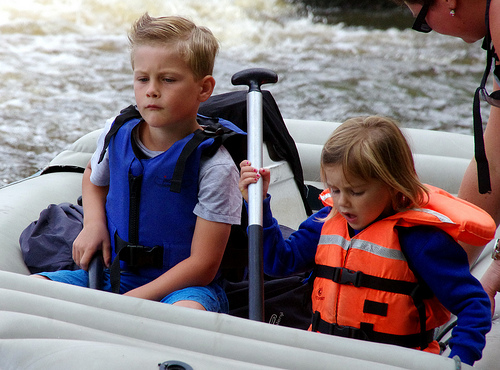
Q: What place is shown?
A: It is a river.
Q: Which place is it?
A: It is a river.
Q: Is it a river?
A: Yes, it is a river.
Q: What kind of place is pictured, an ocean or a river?
A: It is a river.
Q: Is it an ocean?
A: No, it is a river.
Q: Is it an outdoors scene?
A: Yes, it is outdoors.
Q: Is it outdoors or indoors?
A: It is outdoors.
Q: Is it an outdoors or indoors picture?
A: It is outdoors.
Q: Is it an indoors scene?
A: No, it is outdoors.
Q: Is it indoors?
A: No, it is outdoors.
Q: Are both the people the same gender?
A: No, they are both male and female.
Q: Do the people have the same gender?
A: No, they are both male and female.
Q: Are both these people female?
A: No, they are both male and female.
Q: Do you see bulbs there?
A: No, there are no bulbs.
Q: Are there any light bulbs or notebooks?
A: No, there are no light bulbs or notebooks.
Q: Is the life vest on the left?
A: No, the life vest is on the right of the image.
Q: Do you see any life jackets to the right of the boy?
A: Yes, there is a life jacket to the right of the boy.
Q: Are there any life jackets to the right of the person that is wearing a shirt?
A: Yes, there is a life jacket to the right of the boy.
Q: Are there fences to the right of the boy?
A: No, there is a life jacket to the right of the boy.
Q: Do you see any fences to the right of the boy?
A: No, there is a life jacket to the right of the boy.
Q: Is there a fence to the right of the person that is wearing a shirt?
A: No, there is a life jacket to the right of the boy.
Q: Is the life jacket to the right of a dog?
A: No, the life jacket is to the right of the boy.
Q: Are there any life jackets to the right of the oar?
A: Yes, there is a life jacket to the right of the oar.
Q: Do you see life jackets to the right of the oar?
A: Yes, there is a life jacket to the right of the oar.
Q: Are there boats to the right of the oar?
A: No, there is a life jacket to the right of the oar.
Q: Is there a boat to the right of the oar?
A: No, there is a life jacket to the right of the oar.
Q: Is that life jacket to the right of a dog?
A: No, the life jacket is to the right of the oar.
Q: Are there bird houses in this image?
A: No, there are no bird houses.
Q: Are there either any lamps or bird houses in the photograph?
A: No, there are no bird houses or lamps.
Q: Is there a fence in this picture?
A: No, there are no fences.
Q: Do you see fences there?
A: No, there are no fences.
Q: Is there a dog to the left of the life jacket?
A: No, there is a boy to the left of the life jacket.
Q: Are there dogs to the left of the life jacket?
A: No, there is a boy to the left of the life jacket.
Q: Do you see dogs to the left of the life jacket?
A: No, there is a boy to the left of the life jacket.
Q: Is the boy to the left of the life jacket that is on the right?
A: Yes, the boy is to the left of the life jacket.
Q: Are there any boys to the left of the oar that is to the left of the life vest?
A: Yes, there is a boy to the left of the oar.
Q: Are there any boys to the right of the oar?
A: No, the boy is to the left of the oar.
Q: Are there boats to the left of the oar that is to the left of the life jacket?
A: No, there is a boy to the left of the paddle.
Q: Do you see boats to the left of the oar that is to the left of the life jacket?
A: No, there is a boy to the left of the paddle.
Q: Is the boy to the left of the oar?
A: Yes, the boy is to the left of the oar.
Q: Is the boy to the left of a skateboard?
A: No, the boy is to the left of the oar.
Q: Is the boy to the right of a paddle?
A: No, the boy is to the left of a paddle.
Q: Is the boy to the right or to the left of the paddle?
A: The boy is to the left of the paddle.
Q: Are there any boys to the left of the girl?
A: Yes, there is a boy to the left of the girl.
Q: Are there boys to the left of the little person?
A: Yes, there is a boy to the left of the girl.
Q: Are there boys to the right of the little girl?
A: No, the boy is to the left of the girl.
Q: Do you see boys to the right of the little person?
A: No, the boy is to the left of the girl.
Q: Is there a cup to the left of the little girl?
A: No, there is a boy to the left of the girl.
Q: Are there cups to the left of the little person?
A: No, there is a boy to the left of the girl.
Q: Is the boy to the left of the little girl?
A: Yes, the boy is to the left of the girl.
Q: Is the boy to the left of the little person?
A: Yes, the boy is to the left of the girl.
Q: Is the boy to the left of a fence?
A: No, the boy is to the left of the girl.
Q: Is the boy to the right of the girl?
A: No, the boy is to the left of the girl.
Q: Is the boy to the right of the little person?
A: No, the boy is to the left of the girl.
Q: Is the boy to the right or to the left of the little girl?
A: The boy is to the left of the girl.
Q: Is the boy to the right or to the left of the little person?
A: The boy is to the left of the girl.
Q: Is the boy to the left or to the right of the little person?
A: The boy is to the left of the girl.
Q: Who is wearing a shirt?
A: The boy is wearing a shirt.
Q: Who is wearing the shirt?
A: The boy is wearing a shirt.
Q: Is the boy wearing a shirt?
A: Yes, the boy is wearing a shirt.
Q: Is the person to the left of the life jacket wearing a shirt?
A: Yes, the boy is wearing a shirt.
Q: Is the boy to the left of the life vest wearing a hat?
A: No, the boy is wearing a shirt.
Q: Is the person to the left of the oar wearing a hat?
A: No, the boy is wearing a shirt.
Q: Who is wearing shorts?
A: The boy is wearing shorts.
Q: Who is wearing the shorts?
A: The boy is wearing shorts.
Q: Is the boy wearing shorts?
A: Yes, the boy is wearing shorts.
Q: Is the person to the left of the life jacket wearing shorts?
A: Yes, the boy is wearing shorts.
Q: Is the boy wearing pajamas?
A: No, the boy is wearing shorts.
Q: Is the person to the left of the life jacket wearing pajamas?
A: No, the boy is wearing shorts.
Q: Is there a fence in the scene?
A: No, there are no fences.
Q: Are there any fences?
A: No, there are no fences.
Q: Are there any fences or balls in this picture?
A: No, there are no fences or balls.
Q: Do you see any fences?
A: No, there are no fences.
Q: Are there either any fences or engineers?
A: No, there are no fences or engineers.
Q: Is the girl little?
A: Yes, the girl is little.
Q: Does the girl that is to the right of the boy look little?
A: Yes, the girl is little.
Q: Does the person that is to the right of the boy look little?
A: Yes, the girl is little.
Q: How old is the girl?
A: The girl is little.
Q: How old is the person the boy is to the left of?
A: The girl is little.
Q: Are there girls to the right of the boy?
A: Yes, there is a girl to the right of the boy.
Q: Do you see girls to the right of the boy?
A: Yes, there is a girl to the right of the boy.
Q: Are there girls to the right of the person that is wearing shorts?
A: Yes, there is a girl to the right of the boy.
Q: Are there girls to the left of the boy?
A: No, the girl is to the right of the boy.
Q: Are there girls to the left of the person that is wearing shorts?
A: No, the girl is to the right of the boy.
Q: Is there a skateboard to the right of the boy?
A: No, there is a girl to the right of the boy.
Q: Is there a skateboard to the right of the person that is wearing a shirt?
A: No, there is a girl to the right of the boy.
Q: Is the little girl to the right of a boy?
A: Yes, the girl is to the right of a boy.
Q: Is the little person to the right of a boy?
A: Yes, the girl is to the right of a boy.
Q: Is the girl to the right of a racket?
A: No, the girl is to the right of a boy.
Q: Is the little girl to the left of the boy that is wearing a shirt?
A: No, the girl is to the right of the boy.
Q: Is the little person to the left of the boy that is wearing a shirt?
A: No, the girl is to the right of the boy.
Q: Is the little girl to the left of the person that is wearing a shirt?
A: No, the girl is to the right of the boy.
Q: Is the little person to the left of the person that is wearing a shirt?
A: No, the girl is to the right of the boy.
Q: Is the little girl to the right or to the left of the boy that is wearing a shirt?
A: The girl is to the right of the boy.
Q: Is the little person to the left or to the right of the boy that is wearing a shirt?
A: The girl is to the right of the boy.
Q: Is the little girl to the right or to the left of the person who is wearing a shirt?
A: The girl is to the right of the boy.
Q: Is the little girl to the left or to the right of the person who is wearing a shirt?
A: The girl is to the right of the boy.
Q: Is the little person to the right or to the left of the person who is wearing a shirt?
A: The girl is to the right of the boy.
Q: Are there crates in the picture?
A: No, there are no crates.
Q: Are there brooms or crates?
A: No, there are no crates or brooms.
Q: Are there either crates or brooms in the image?
A: No, there are no crates or brooms.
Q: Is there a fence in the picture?
A: No, there are no fences.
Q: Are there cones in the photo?
A: No, there are no cones.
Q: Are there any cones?
A: No, there are no cones.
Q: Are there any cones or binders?
A: No, there are no cones or binders.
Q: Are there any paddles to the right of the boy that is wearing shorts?
A: Yes, there is a paddle to the right of the boy.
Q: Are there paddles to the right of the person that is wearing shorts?
A: Yes, there is a paddle to the right of the boy.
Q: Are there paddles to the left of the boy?
A: No, the paddle is to the right of the boy.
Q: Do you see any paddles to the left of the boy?
A: No, the paddle is to the right of the boy.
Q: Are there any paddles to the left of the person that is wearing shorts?
A: No, the paddle is to the right of the boy.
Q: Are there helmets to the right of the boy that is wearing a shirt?
A: No, there is a paddle to the right of the boy.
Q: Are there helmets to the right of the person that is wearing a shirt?
A: No, there is a paddle to the right of the boy.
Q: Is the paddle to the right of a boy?
A: Yes, the paddle is to the right of a boy.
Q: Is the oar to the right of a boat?
A: No, the oar is to the right of a boy.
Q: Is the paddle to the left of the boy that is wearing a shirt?
A: No, the paddle is to the right of the boy.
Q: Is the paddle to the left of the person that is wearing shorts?
A: No, the paddle is to the right of the boy.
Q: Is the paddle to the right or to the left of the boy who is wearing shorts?
A: The paddle is to the right of the boy.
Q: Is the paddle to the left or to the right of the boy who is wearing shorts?
A: The paddle is to the right of the boy.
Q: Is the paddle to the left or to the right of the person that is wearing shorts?
A: The paddle is to the right of the boy.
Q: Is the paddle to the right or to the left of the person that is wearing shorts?
A: The paddle is to the right of the boy.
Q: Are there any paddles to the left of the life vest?
A: Yes, there is a paddle to the left of the life vest.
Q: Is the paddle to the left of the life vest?
A: Yes, the paddle is to the left of the life vest.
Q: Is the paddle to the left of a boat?
A: No, the paddle is to the left of the life vest.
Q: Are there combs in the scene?
A: No, there are no combs.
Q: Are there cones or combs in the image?
A: No, there are no combs or cones.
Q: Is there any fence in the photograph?
A: No, there are no fences.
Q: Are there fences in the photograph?
A: No, there are no fences.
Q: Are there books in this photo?
A: No, there are no books.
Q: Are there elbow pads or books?
A: No, there are no books or elbow pads.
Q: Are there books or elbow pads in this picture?
A: No, there are no books or elbow pads.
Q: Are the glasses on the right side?
A: Yes, the glasses are on the right of the image.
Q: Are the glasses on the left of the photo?
A: No, the glasses are on the right of the image.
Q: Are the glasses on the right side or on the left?
A: The glasses are on the right of the image.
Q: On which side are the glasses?
A: The glasses are on the right of the image.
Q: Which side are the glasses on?
A: The glasses are on the right of the image.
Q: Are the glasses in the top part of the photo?
A: Yes, the glasses are in the top of the image.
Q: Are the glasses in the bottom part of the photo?
A: No, the glasses are in the top of the image.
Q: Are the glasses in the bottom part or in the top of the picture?
A: The glasses are in the top of the image.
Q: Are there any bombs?
A: No, there are no bombs.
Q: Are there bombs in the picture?
A: No, there are no bombs.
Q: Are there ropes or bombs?
A: No, there are no bombs or ropes.